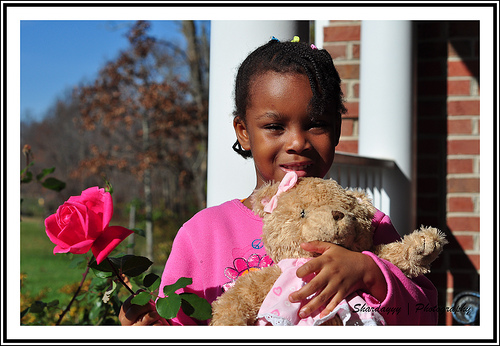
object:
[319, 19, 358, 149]
wall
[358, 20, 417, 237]
column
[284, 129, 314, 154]
nose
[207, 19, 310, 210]
column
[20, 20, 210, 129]
sky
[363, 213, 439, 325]
girl's arm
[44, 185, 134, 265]
flower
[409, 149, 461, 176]
ground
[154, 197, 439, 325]
shirt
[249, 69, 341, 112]
forehead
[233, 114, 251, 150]
ear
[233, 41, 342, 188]
head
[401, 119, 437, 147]
ground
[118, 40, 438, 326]
girl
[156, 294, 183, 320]
leaf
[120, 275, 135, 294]
stem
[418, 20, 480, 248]
brown wall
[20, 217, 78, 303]
grass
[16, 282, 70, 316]
ground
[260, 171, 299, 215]
bow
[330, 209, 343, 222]
nose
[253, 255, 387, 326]
clothes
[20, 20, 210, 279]
trees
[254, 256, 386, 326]
fabric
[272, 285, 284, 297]
hearts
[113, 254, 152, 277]
leaves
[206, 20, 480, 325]
building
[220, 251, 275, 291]
design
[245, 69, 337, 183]
face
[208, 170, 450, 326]
bear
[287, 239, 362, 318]
hand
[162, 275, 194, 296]
leaves